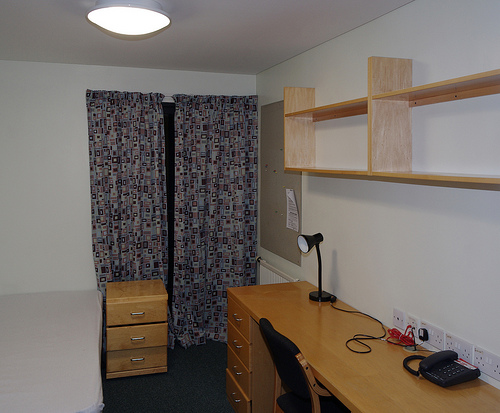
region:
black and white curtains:
[88, 84, 258, 339]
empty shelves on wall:
[272, 65, 498, 195]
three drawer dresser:
[103, 275, 167, 382]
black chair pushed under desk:
[256, 324, 340, 411]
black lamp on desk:
[293, 230, 334, 307]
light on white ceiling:
[85, 6, 182, 34]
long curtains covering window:
[91, 95, 256, 344]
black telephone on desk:
[404, 341, 466, 386]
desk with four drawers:
[223, 284, 428, 411]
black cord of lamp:
[322, 285, 379, 364]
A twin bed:
[0, 289, 100, 411]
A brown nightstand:
[104, 277, 176, 381]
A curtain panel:
[80, 85, 169, 280]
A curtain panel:
[171, 87, 254, 283]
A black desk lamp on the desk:
[295, 223, 349, 306]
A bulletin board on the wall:
[253, 116, 285, 266]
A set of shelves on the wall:
[272, 66, 496, 192]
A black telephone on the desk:
[407, 338, 484, 396]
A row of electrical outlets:
[390, 314, 499, 379]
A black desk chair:
[255, 312, 334, 409]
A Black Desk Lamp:
[279, 222, 367, 330]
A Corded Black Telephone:
[390, 344, 491, 401]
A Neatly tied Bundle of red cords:
[374, 289, 421, 361]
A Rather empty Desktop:
[233, 277, 411, 411]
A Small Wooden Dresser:
[96, 275, 199, 390]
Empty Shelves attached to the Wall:
[266, 34, 495, 219]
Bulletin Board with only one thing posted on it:
[249, 85, 314, 290]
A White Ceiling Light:
[55, 0, 224, 60]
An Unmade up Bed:
[1, 239, 115, 411]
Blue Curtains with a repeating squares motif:
[73, 74, 263, 362]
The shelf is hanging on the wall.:
[248, 0, 498, 390]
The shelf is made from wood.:
[266, 47, 499, 256]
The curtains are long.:
[75, 71, 270, 373]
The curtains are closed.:
[66, 68, 274, 365]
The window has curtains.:
[71, 72, 271, 371]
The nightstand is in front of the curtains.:
[0, 74, 265, 381]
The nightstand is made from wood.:
[88, 264, 183, 391]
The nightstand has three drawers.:
[89, 260, 186, 389]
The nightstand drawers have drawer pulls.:
[81, 265, 183, 395]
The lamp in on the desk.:
[210, 218, 499, 411]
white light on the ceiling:
[82, 0, 175, 45]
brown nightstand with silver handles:
[100, 277, 172, 383]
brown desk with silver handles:
[223, 279, 499, 411]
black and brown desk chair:
[255, 314, 345, 411]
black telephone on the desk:
[401, 346, 483, 388]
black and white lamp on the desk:
[293, 228, 340, 306]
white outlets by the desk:
[389, 302, 498, 384]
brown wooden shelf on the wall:
[278, 50, 498, 195]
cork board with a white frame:
[253, 98, 308, 273]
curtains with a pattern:
[82, 85, 262, 350]